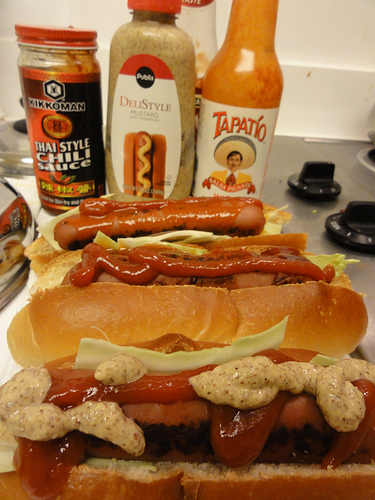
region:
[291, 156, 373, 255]
The knobs on the stove.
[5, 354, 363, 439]
The mustard on the hot dog.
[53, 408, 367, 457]
The hot dog with mustard on it.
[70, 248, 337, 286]
The hot dog in the middle.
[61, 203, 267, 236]
The hot dog at the top.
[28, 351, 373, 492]
The hot dog bun of the hot dog at the bottom.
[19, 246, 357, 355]
The hot dog bun of the hot dog in the middle.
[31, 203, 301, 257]
The hot dog bun of the hot dog at the top.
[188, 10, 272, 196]
The bottle of hot sauce.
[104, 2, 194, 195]
The bottle of mustard.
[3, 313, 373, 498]
hotdog topped with mustard ketchup and cabbage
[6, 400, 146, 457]
mustard on a hotdog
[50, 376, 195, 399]
ketchup on a hotdog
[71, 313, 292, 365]
piece of cabbage in a hotdog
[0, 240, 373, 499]
two hot dogs loaded with toppings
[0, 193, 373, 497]
three hot dogs loaded with toppings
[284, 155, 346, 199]
black dial on a silver appliance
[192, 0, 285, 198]
bottle of tapitio sauce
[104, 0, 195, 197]
bottle of deli style mustard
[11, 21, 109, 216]
jar of Thai chilli sauce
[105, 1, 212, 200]
Bottle of deli style mustard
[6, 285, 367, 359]
Hot dog bun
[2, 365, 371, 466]
mustard and ketchup on a hot dog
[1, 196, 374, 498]
hot dogs with ketchup on them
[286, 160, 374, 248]
dials on the oven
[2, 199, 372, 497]
hot dogs on buns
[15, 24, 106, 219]
jar of chili sauce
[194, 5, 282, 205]
bottle of hot sauce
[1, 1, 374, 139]
white walls behind the food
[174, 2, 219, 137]
bottle of ketchup behind the mustard and hot sauce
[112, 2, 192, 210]
The bottle of mustard.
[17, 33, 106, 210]
The bottle of chili sauce.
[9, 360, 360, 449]
The mustard on the hot dog.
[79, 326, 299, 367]
The slice of cheese next to the mustard on the hot dog.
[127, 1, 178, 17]
The red cap on the mustard bottle.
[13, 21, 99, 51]
The red lid on the chili sauce jar.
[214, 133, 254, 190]
The man on the hot sauce label.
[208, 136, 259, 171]
The sombrero the man on the label is wearing.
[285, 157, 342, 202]
A black stove knob.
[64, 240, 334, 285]
Ketchup on a hotdog.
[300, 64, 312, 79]
A speck on the wall.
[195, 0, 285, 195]
A bottle of hot sauce.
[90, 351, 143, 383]
Deli mustard on a hot dog.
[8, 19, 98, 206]
A jar of chili sauce.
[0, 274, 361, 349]
A hot dog bun.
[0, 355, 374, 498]
A delicious hot dog.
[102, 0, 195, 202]
A bottle of deli mustard.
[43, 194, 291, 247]
A hot dog covered in ketchup and hot sauce.